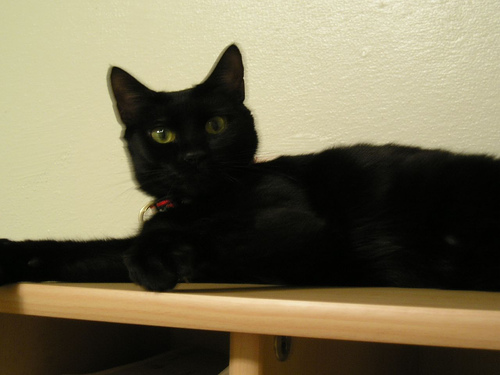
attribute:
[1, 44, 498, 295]
cat — black, resting, laying down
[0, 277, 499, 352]
shelf — wooden, wood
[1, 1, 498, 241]
wall — light yellow, cream colored, stucco, white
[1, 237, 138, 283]
right paw — outstretched, soft, furry, black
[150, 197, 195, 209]
collar — red, cloth, black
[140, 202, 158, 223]
metal ring — brass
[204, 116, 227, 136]
left eye — green, bright green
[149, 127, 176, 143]
right eye — green, glassy, bright green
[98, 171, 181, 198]
whiskers — long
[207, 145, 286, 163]
whiskers — long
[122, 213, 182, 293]
left paw — soft, furry, black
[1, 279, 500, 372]
table — wooden, light colored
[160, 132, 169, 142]
pupil — slit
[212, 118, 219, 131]
pupil — slit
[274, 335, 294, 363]
shelf support — metal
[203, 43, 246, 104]
left ear — pointy, black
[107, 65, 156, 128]
right ear — pointy, black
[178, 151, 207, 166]
nose — small, black